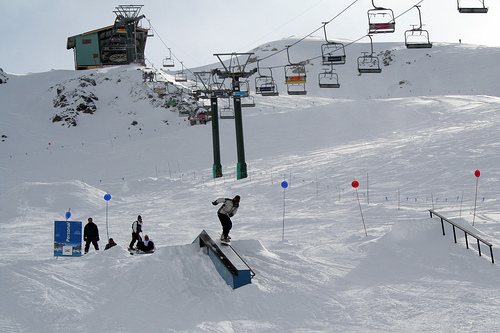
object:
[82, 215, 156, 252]
people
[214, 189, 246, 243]
snowboarder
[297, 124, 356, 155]
snow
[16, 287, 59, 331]
snow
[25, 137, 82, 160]
snow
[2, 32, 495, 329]
hillside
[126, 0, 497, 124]
ski lift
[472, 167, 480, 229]
pole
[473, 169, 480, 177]
red circle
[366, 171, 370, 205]
pole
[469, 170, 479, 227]
circle stick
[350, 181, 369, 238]
circle stick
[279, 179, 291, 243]
circle stick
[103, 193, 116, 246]
circle stick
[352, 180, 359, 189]
red circle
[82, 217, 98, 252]
person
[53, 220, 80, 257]
sign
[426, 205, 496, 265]
fence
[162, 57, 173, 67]
chair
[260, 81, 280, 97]
chair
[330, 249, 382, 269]
snow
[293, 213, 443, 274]
ground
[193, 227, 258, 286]
snowboarder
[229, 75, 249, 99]
chair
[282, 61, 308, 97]
chair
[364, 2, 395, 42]
chair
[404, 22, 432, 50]
chair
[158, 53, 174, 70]
chair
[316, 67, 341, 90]
chair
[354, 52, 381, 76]
chair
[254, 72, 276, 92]
chair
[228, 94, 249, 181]
metal pole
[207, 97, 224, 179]
metal pole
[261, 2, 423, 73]
ski-lift wire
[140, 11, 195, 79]
ski-lift wire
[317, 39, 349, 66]
cahir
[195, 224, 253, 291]
ramp